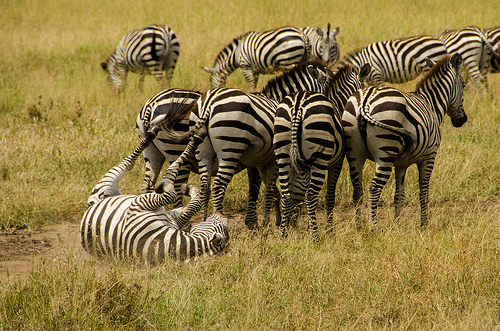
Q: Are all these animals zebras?
A: Yes, all the animals are zebras.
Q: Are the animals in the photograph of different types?
A: No, all the animals are zebras.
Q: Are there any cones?
A: No, there are no cones.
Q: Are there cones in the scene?
A: No, there are no cones.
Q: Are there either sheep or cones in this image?
A: No, there are no cones or sheep.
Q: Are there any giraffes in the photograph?
A: No, there are no giraffes.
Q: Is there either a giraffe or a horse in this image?
A: No, there are no giraffes or horses.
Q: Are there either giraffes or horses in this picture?
A: No, there are no giraffes or horses.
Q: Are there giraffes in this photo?
A: No, there are no giraffes.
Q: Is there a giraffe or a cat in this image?
A: No, there are no giraffes or cats.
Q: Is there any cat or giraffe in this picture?
A: No, there are no giraffes or cats.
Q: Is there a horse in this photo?
A: No, there are no horses.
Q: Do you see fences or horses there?
A: No, there are no horses or fences.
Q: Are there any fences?
A: No, there are no fences.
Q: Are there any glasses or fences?
A: No, there are no fences or glasses.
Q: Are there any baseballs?
A: No, there are no baseballs.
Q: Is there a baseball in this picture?
A: No, there are no baseballs.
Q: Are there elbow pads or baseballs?
A: No, there are no baseballs or elbow pads.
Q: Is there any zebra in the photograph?
A: Yes, there is a zebra.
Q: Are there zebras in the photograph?
A: Yes, there is a zebra.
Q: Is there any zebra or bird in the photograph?
A: Yes, there is a zebra.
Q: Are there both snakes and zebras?
A: No, there is a zebra but no snakes.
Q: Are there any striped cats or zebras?
A: Yes, there is a striped zebra.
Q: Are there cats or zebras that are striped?
A: Yes, the zebra is striped.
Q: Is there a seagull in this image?
A: No, there are no seagulls.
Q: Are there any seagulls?
A: No, there are no seagulls.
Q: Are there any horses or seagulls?
A: No, there are no seagulls or horses.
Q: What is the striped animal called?
A: The animal is a zebra.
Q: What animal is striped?
A: The animal is a zebra.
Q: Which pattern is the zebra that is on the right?
A: The zebra is striped.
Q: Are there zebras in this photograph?
A: Yes, there is a zebra.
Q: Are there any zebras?
A: Yes, there is a zebra.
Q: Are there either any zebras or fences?
A: Yes, there is a zebra.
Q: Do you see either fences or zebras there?
A: Yes, there is a zebra.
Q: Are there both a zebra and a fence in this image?
A: No, there is a zebra but no fences.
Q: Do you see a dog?
A: No, there are no dogs.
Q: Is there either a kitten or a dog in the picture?
A: No, there are no dogs or kittens.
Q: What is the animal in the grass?
A: The animal is a zebra.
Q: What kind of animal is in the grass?
A: The animal is a zebra.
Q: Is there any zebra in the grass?
A: Yes, there is a zebra in the grass.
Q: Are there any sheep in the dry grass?
A: No, there is a zebra in the grass.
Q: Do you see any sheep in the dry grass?
A: No, there is a zebra in the grass.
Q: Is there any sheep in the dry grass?
A: No, there is a zebra in the grass.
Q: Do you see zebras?
A: Yes, there is a zebra.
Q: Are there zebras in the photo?
A: Yes, there is a zebra.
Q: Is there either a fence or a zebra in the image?
A: Yes, there is a zebra.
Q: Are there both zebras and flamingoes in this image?
A: No, there is a zebra but no flamingoes.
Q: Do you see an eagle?
A: No, there are no eagles.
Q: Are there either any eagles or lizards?
A: No, there are no eagles or lizards.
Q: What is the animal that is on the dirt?
A: The animal is a zebra.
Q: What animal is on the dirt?
A: The animal is a zebra.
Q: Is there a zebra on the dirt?
A: Yes, there is a zebra on the dirt.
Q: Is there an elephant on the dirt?
A: No, there is a zebra on the dirt.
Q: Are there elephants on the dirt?
A: No, there is a zebra on the dirt.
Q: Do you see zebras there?
A: Yes, there is a zebra.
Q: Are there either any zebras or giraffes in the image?
A: Yes, there is a zebra.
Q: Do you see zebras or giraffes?
A: Yes, there is a zebra.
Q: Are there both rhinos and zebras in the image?
A: No, there is a zebra but no rhinos.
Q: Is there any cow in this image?
A: No, there are no cows.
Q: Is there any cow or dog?
A: No, there are no cows or dogs.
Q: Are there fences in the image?
A: No, there are no fences.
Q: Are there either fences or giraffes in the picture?
A: No, there are no fences or giraffes.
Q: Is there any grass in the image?
A: Yes, there is grass.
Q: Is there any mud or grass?
A: Yes, there is grass.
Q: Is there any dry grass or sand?
A: Yes, there is dry grass.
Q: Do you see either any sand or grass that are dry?
A: Yes, the grass is dry.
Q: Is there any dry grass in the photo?
A: Yes, there is dry grass.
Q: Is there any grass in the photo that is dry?
A: Yes, there is dry grass.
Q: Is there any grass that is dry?
A: Yes, there is grass that is dry.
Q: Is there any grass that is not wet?
A: Yes, there is dry grass.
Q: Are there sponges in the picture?
A: No, there are no sponges.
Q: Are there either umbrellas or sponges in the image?
A: No, there are no sponges or umbrellas.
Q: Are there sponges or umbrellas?
A: No, there are no sponges or umbrellas.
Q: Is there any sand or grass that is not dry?
A: No, there is grass but it is dry.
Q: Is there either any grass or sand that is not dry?
A: No, there is grass but it is dry.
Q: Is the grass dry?
A: Yes, the grass is dry.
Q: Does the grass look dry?
A: Yes, the grass is dry.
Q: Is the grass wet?
A: No, the grass is dry.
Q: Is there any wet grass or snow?
A: No, there is grass but it is dry.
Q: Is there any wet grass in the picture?
A: No, there is grass but it is dry.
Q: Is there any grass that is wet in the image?
A: No, there is grass but it is dry.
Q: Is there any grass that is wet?
A: No, there is grass but it is dry.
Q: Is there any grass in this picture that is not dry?
A: No, there is grass but it is dry.